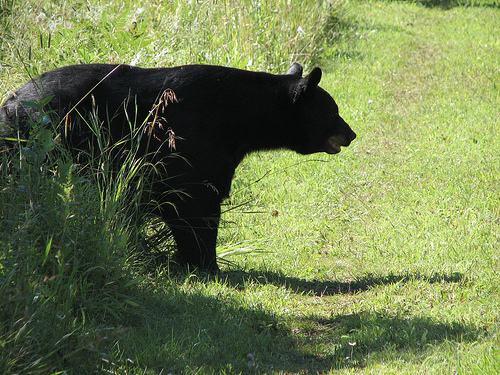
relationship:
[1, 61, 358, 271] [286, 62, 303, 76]
bear has ear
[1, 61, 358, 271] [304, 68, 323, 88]
bear has ear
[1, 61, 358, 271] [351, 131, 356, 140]
bear has nose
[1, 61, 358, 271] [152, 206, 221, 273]
bear has legs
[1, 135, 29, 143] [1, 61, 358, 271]
grass next to bear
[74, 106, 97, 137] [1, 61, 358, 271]
grass next to bear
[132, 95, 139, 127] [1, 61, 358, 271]
grass next to bear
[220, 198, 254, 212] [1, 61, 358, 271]
grass next to bear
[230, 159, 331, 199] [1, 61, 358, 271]
grass next to bear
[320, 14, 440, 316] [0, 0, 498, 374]
track running through grass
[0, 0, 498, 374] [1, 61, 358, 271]
grass extends behind bear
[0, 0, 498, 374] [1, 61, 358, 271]
grass extends in front of bear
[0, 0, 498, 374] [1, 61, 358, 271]
grass around bear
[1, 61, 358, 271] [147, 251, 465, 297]
bear casts shadow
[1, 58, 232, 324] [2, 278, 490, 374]
grass clump casts shadow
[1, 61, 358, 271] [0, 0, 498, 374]
bear going to grass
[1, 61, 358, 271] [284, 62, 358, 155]
bear has head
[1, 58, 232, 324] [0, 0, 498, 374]
grass clump growing in grass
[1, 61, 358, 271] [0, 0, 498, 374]
bear standing in grass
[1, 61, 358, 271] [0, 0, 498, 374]
bear walking through grass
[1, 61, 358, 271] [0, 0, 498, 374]
bear prowling in grass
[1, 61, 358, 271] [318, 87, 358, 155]
bear has face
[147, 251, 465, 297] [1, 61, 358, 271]
shadow from bear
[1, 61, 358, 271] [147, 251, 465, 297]
bear casting shadow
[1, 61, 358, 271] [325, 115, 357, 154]
bear has snout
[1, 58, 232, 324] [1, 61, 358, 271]
grass clump next to bear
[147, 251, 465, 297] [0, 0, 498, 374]
shadow falls on grass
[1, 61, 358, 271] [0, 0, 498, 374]
bear standing on grass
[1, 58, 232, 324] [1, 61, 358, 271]
grass clump to right of bear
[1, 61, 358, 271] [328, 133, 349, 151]
bear has mouth